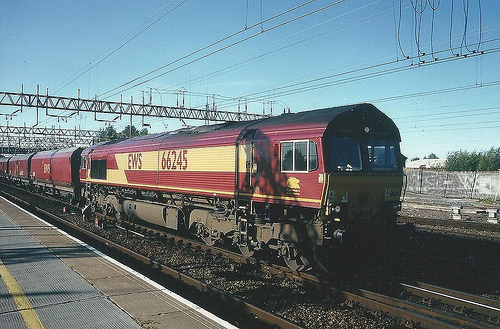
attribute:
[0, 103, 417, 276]
train — red, electric, brown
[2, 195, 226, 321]
platform — white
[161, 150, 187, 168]
numbers — burgundy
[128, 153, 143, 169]
letters — burgundy, red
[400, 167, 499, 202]
wall — cement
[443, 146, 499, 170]
tree — green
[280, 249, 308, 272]
wheels — brown, black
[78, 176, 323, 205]
stripe — yellow, tan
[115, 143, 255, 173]
logo — yellow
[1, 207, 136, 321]
bricks — grey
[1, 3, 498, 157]
sky — blue, clear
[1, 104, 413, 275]
railroad car — yellow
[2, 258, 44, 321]
line — yellow, white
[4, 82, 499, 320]
railway station — railway station